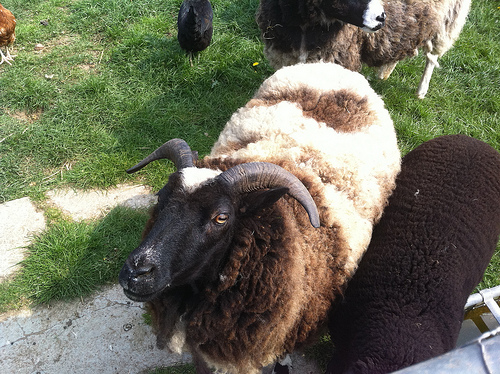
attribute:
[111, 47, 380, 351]
sheep — brown, browny, white, whitey, vwhite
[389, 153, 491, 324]
sheep — brown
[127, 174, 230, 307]
face — black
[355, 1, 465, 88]
sheep — brown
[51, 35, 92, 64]
grass — green